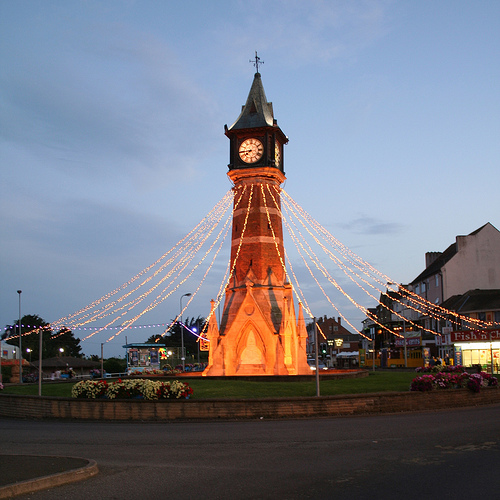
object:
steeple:
[223, 51, 289, 145]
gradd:
[259, 416, 264, 421]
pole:
[180, 301, 185, 372]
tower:
[200, 47, 308, 375]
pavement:
[147, 426, 236, 459]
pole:
[200, 51, 313, 377]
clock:
[233, 129, 268, 166]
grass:
[1, 369, 441, 399]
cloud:
[174, 262, 211, 317]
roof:
[410, 220, 500, 286]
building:
[361, 222, 500, 367]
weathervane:
[249, 51, 264, 73]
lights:
[3, 184, 498, 376]